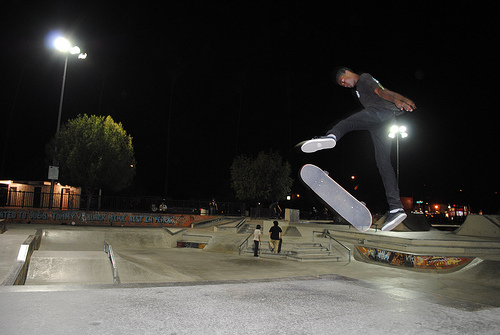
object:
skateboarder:
[294, 67, 416, 231]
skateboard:
[300, 164, 373, 232]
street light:
[48, 36, 88, 210]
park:
[0, 205, 500, 335]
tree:
[44, 113, 138, 211]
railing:
[0, 188, 242, 215]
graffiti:
[107, 215, 174, 224]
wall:
[0, 209, 217, 227]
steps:
[286, 243, 343, 263]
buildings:
[0, 178, 81, 212]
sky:
[217, 17, 238, 30]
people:
[253, 225, 261, 258]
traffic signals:
[351, 176, 355, 180]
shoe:
[294, 136, 336, 153]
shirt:
[355, 73, 404, 117]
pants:
[325, 106, 405, 210]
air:
[363, 10, 456, 57]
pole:
[52, 56, 67, 165]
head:
[335, 67, 360, 88]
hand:
[395, 98, 418, 112]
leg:
[327, 113, 367, 140]